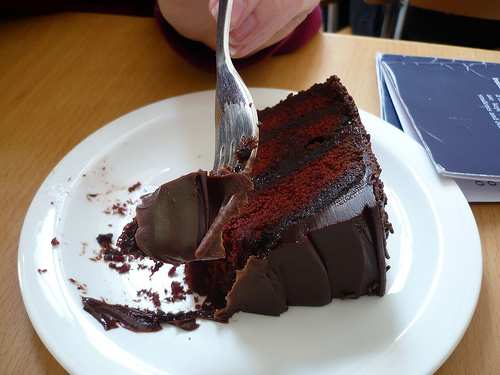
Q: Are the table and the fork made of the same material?
A: No, the table is made of wood and the fork is made of metal.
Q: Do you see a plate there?
A: Yes, there is a plate.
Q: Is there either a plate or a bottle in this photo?
A: Yes, there is a plate.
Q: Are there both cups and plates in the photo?
A: No, there is a plate but no cups.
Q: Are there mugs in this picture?
A: No, there are no mugs.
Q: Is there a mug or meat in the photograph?
A: No, there are no mugs or meat.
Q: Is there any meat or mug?
A: No, there are no mugs or meat.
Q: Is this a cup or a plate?
A: This is a plate.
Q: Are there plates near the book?
A: Yes, there is a plate near the book.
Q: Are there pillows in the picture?
A: No, there are no pillows.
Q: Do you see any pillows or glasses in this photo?
A: No, there are no pillows or glasses.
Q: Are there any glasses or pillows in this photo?
A: No, there are no pillows or glasses.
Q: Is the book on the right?
A: Yes, the book is on the right of the image.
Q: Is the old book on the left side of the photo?
A: No, the book is on the right of the image.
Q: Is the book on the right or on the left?
A: The book is on the right of the image.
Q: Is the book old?
A: Yes, the book is old.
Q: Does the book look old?
A: Yes, the book is old.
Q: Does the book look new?
A: No, the book is old.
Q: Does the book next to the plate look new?
A: No, the book is old.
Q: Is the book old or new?
A: The book is old.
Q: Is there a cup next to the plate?
A: No, there is a book next to the plate.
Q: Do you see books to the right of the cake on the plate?
A: Yes, there is a book to the right of the cake.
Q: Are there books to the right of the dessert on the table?
A: Yes, there is a book to the right of the cake.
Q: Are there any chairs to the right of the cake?
A: No, there is a book to the right of the cake.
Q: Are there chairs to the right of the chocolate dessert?
A: No, there is a book to the right of the cake.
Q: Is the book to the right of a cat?
A: No, the book is to the right of the cake.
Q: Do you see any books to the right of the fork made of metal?
A: Yes, there is a book to the right of the fork.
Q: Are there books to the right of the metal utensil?
A: Yes, there is a book to the right of the fork.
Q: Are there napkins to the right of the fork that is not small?
A: No, there is a book to the right of the fork.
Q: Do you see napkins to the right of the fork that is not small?
A: No, there is a book to the right of the fork.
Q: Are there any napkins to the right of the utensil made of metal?
A: No, there is a book to the right of the fork.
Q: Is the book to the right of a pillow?
A: No, the book is to the right of the fork.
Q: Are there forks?
A: Yes, there is a fork.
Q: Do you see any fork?
A: Yes, there is a fork.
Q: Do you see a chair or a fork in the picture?
A: Yes, there is a fork.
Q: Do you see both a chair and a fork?
A: No, there is a fork but no chairs.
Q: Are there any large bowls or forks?
A: Yes, there is a large fork.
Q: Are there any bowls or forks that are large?
A: Yes, the fork is large.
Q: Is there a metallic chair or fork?
A: Yes, there is a metal fork.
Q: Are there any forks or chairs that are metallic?
A: Yes, the fork is metallic.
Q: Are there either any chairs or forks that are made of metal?
A: Yes, the fork is made of metal.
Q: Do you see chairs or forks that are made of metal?
A: Yes, the fork is made of metal.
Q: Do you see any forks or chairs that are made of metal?
A: Yes, the fork is made of metal.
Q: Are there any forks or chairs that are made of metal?
A: Yes, the fork is made of metal.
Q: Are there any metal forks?
A: Yes, there is a metal fork.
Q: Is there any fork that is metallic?
A: Yes, there is a fork that is metallic.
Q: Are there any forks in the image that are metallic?
A: Yes, there is a fork that is metallic.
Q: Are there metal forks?
A: Yes, there is a fork that is made of metal.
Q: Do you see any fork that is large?
A: Yes, there is a large fork.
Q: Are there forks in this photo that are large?
A: Yes, there is a fork that is large.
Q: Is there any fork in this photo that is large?
A: Yes, there is a fork that is large.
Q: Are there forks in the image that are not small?
A: Yes, there is a large fork.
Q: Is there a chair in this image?
A: No, there are no chairs.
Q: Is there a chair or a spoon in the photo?
A: No, there are no chairs or spoons.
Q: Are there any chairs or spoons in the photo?
A: No, there are no chairs or spoons.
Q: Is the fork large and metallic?
A: Yes, the fork is large and metallic.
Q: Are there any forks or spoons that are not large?
A: No, there is a fork but it is large.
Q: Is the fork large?
A: Yes, the fork is large.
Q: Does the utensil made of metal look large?
A: Yes, the fork is large.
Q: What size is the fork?
A: The fork is large.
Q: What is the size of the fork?
A: The fork is large.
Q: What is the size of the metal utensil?
A: The fork is large.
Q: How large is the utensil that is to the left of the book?
A: The fork is large.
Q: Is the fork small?
A: No, the fork is large.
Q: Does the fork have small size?
A: No, the fork is large.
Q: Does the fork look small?
A: No, the fork is large.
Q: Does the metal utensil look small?
A: No, the fork is large.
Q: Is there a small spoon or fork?
A: No, there is a fork but it is large.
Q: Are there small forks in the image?
A: No, there is a fork but it is large.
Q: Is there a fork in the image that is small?
A: No, there is a fork but it is large.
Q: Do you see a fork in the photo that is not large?
A: No, there is a fork but it is large.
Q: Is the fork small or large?
A: The fork is large.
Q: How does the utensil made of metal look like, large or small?
A: The fork is large.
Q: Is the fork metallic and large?
A: Yes, the fork is metallic and large.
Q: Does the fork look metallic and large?
A: Yes, the fork is metallic and large.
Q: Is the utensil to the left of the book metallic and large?
A: Yes, the fork is metallic and large.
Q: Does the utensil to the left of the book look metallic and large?
A: Yes, the fork is metallic and large.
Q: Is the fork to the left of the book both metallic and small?
A: No, the fork is metallic but large.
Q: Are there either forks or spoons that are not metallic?
A: No, there is a fork but it is metallic.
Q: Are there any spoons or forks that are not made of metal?
A: No, there is a fork but it is made of metal.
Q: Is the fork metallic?
A: Yes, the fork is metallic.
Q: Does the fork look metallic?
A: Yes, the fork is metallic.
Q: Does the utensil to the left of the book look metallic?
A: Yes, the fork is metallic.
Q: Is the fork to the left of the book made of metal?
A: Yes, the fork is made of metal.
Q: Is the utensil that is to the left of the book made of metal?
A: Yes, the fork is made of metal.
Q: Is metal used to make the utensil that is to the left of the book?
A: Yes, the fork is made of metal.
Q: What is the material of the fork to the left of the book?
A: The fork is made of metal.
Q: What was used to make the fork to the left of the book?
A: The fork is made of metal.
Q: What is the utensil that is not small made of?
A: The fork is made of metal.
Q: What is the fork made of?
A: The fork is made of metal.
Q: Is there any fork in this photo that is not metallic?
A: No, there is a fork but it is metallic.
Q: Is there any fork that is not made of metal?
A: No, there is a fork but it is made of metal.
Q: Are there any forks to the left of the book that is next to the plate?
A: Yes, there is a fork to the left of the book.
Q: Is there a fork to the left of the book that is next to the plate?
A: Yes, there is a fork to the left of the book.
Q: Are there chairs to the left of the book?
A: No, there is a fork to the left of the book.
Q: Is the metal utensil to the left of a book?
A: Yes, the fork is to the left of a book.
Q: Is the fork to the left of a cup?
A: No, the fork is to the left of a book.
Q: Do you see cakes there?
A: Yes, there is a cake.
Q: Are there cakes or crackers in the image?
A: Yes, there is a cake.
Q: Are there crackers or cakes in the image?
A: Yes, there is a cake.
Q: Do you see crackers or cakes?
A: Yes, there is a cake.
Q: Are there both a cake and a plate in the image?
A: Yes, there are both a cake and a plate.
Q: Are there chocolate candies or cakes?
A: Yes, there is a chocolate cake.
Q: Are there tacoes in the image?
A: No, there are no tacoes.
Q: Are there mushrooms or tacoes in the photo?
A: No, there are no tacoes or mushrooms.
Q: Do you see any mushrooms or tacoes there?
A: No, there are no tacoes or mushrooms.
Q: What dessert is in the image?
A: The dessert is a cake.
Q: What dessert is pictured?
A: The dessert is a cake.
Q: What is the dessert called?
A: The dessert is a cake.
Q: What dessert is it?
A: The dessert is a cake.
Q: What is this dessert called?
A: This is a cake.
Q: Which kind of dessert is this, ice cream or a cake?
A: This is a cake.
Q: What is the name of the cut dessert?
A: The dessert is a cake.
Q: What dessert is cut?
A: The dessert is a cake.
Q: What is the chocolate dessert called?
A: The dessert is a cake.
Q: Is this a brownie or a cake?
A: This is a cake.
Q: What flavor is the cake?
A: This is a chocolate cake.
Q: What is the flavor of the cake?
A: This is a chocolate cake.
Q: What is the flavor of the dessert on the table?
A: This is a chocolate cake.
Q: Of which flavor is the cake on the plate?
A: This is a chocolate cake.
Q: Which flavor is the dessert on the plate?
A: This is a chocolate cake.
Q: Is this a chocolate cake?
A: Yes, this is a chocolate cake.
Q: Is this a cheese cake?
A: No, this is a chocolate cake.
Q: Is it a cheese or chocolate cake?
A: This is a chocolate cake.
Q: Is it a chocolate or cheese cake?
A: This is a chocolate cake.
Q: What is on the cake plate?
A: The cake is on the plate.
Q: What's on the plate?
A: The cake is on the plate.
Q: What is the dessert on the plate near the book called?
A: The dessert is a cake.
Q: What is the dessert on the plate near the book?
A: The dessert is a cake.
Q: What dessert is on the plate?
A: The dessert is a cake.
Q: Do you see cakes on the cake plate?
A: Yes, there is a cake on the plate.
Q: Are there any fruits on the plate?
A: No, there is a cake on the plate.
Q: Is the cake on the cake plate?
A: Yes, the cake is on the plate.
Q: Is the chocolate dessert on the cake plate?
A: Yes, the cake is on the plate.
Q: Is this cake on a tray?
A: No, the cake is on the plate.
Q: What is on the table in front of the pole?
A: The cake is on the table.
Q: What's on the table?
A: The cake is on the table.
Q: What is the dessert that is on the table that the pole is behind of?
A: The dessert is a cake.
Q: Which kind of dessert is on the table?
A: The dessert is a cake.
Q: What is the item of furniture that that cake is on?
A: The piece of furniture is a table.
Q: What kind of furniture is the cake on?
A: The cake is on the table.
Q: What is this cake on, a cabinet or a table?
A: The cake is on a table.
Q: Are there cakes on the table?
A: Yes, there is a cake on the table.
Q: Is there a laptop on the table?
A: No, there is a cake on the table.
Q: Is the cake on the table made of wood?
A: Yes, the cake is on the table.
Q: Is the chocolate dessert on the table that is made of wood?
A: Yes, the cake is on the table.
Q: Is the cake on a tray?
A: No, the cake is on the table.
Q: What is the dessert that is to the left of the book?
A: The dessert is a cake.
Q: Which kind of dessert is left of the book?
A: The dessert is a cake.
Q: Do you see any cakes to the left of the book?
A: Yes, there is a cake to the left of the book.